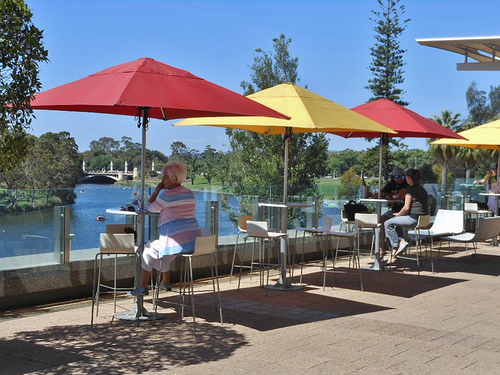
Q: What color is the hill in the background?
A: Green.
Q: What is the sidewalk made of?
A: Bricks.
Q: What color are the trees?
A: Green.